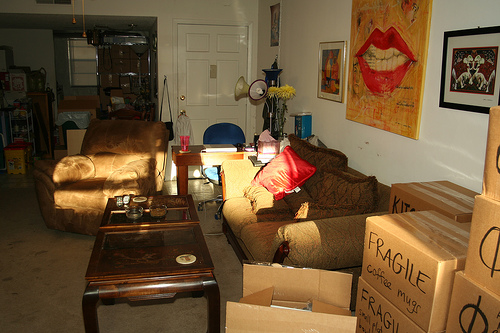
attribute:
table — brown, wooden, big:
[105, 197, 162, 284]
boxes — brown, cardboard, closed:
[360, 217, 472, 329]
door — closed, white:
[180, 23, 244, 126]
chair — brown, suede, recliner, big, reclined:
[92, 132, 124, 201]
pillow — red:
[271, 148, 323, 198]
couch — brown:
[268, 139, 342, 259]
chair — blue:
[206, 124, 245, 146]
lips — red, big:
[365, 31, 403, 92]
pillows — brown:
[294, 139, 375, 214]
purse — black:
[167, 87, 177, 148]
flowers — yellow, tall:
[267, 79, 292, 104]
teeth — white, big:
[373, 54, 377, 64]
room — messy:
[28, 54, 347, 308]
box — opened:
[249, 261, 318, 331]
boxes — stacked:
[443, 108, 495, 332]